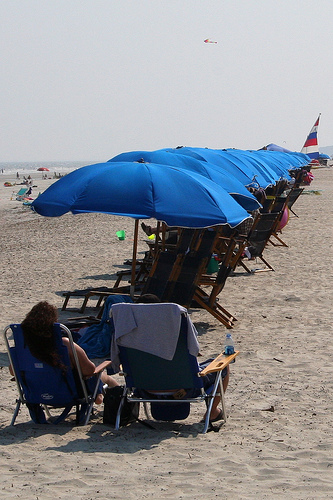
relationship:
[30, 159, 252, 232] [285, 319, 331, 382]
blue umbrellas over beach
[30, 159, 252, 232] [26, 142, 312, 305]
blue umbrellas lined up in row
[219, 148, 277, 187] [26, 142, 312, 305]
umbrella lined up in row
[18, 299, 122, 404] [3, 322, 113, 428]
person sitting in beach chair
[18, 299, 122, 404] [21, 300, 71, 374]
person has brunette hair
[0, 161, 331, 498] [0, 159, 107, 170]
beach beside ocean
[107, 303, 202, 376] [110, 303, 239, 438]
shirt on back of beach chair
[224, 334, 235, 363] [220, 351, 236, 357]
bottle sitting in cup holder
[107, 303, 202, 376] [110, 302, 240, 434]
shirt hanging over back of beach chair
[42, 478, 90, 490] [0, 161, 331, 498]
track in beach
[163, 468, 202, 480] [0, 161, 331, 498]
track in beach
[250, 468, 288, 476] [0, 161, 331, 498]
track in beach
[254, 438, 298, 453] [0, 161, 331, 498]
track in beach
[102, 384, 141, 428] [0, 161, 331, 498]
bag on beach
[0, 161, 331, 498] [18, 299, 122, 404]
beach under person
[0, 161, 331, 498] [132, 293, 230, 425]
beach under person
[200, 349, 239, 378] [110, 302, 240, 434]
arm of beach chair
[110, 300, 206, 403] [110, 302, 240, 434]
back of beach chair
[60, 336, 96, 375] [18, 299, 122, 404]
arm of person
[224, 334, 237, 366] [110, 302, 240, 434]
bottle on beach chair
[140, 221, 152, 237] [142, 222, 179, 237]
foot of a person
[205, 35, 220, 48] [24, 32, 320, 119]
plane in sky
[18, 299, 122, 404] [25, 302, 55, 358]
person has long hair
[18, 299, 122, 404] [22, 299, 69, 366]
person has brown hair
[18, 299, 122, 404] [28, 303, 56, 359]
person as curly hair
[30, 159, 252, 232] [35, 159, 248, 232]
blue umbrellas of blue umbrellas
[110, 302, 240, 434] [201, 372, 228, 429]
beach chair with metal legs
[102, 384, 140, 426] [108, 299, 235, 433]
bag with chairs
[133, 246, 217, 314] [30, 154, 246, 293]
wooden chairs under umbrellas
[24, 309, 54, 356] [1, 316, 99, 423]
brunette hair draped on chair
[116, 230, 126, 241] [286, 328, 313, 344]
bucket in sand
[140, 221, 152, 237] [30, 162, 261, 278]
foot of person under umbrella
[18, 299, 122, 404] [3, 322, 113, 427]
person sitting in a beach beach chair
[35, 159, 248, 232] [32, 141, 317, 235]
blue umbrellas in a row